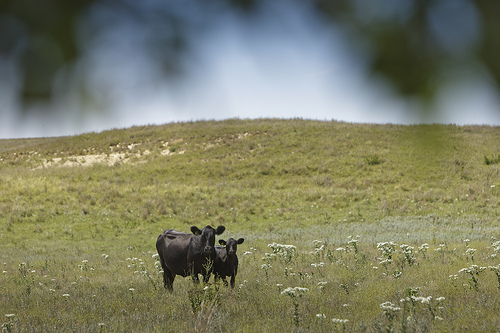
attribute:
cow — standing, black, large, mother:
[151, 219, 227, 291]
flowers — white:
[377, 287, 447, 333]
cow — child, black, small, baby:
[214, 233, 245, 291]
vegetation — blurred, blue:
[0, 1, 498, 121]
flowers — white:
[369, 234, 444, 273]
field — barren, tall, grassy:
[4, 115, 499, 333]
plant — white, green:
[262, 238, 485, 275]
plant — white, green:
[276, 281, 314, 333]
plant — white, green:
[459, 262, 488, 288]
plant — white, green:
[126, 253, 151, 282]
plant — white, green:
[376, 239, 396, 266]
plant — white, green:
[380, 295, 401, 325]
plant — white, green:
[401, 241, 418, 266]